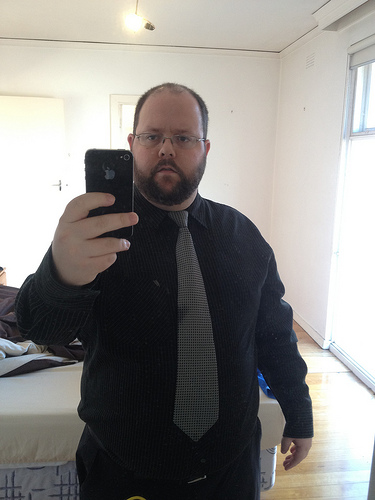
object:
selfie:
[33, 84, 225, 268]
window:
[324, 36, 374, 388]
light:
[119, 9, 164, 42]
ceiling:
[3, 6, 334, 58]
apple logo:
[102, 167, 119, 182]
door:
[105, 92, 212, 212]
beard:
[130, 143, 208, 206]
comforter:
[1, 277, 81, 371]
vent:
[298, 48, 322, 71]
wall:
[275, 13, 375, 350]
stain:
[176, 299, 190, 324]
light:
[311, 346, 374, 499]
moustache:
[149, 159, 190, 179]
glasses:
[126, 128, 211, 154]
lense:
[174, 130, 195, 149]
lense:
[128, 125, 161, 152]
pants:
[76, 417, 260, 498]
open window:
[338, 48, 371, 144]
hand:
[49, 191, 139, 286]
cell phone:
[83, 149, 136, 239]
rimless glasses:
[124, 130, 211, 147]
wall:
[29, 25, 347, 87]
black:
[122, 184, 131, 209]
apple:
[101, 163, 118, 181]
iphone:
[85, 149, 134, 240]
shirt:
[18, 183, 318, 462]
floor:
[260, 318, 373, 496]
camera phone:
[56, 73, 287, 262]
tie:
[168, 209, 218, 441]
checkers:
[186, 303, 207, 399]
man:
[17, 79, 320, 495]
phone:
[81, 143, 142, 247]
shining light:
[312, 364, 374, 499]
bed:
[3, 283, 285, 496]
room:
[0, 1, 372, 498]